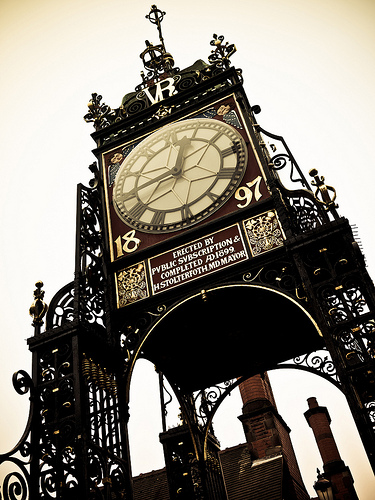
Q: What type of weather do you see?
A: It is cloudless.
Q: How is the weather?
A: It is cloudless.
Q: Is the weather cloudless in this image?
A: Yes, it is cloudless.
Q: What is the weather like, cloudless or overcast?
A: It is cloudless.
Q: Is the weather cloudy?
A: No, it is cloudless.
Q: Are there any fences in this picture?
A: No, there are no fences.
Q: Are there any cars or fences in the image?
A: No, there are no fences or cars.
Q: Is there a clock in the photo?
A: Yes, there is a clock.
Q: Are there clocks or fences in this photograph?
A: Yes, there is a clock.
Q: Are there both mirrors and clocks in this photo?
A: No, there is a clock but no mirrors.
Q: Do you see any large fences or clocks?
A: Yes, there is a large clock.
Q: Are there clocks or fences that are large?
A: Yes, the clock is large.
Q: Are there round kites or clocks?
A: Yes, there is a round clock.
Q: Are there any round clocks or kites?
A: Yes, there is a round clock.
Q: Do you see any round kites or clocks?
A: Yes, there is a round clock.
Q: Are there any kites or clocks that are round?
A: Yes, the clock is round.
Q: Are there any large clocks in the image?
A: Yes, there is a large clock.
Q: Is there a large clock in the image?
A: Yes, there is a large clock.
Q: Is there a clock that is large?
A: Yes, there is a clock that is large.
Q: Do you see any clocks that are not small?
A: Yes, there is a large clock.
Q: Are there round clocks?
A: Yes, there is a round clock.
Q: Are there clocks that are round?
A: Yes, there is a clock that is round.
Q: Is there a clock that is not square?
A: Yes, there is a round clock.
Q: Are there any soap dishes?
A: No, there are no soap dishes.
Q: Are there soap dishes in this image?
A: No, there are no soap dishes.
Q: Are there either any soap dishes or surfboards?
A: No, there are no soap dishes or surfboards.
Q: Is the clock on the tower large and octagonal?
A: No, the clock is large but round.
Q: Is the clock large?
A: Yes, the clock is large.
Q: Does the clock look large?
A: Yes, the clock is large.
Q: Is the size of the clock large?
A: Yes, the clock is large.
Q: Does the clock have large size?
A: Yes, the clock is large.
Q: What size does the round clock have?
A: The clock has large size.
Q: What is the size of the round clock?
A: The clock is large.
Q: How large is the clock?
A: The clock is large.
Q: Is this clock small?
A: No, the clock is large.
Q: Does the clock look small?
A: No, the clock is large.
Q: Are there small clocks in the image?
A: No, there is a clock but it is large.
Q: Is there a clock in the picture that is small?
A: No, there is a clock but it is large.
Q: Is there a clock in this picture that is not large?
A: No, there is a clock but it is large.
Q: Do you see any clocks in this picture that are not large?
A: No, there is a clock but it is large.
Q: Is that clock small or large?
A: The clock is large.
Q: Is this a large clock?
A: Yes, this is a large clock.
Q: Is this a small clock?
A: No, this is a large clock.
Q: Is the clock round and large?
A: Yes, the clock is round and large.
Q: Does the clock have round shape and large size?
A: Yes, the clock is round and large.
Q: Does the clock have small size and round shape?
A: No, the clock is round but large.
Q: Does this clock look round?
A: Yes, the clock is round.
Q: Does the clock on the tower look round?
A: Yes, the clock is round.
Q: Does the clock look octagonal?
A: No, the clock is round.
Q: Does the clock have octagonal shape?
A: No, the clock is round.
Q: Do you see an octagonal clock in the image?
A: No, there is a clock but it is round.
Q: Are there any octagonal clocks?
A: No, there is a clock but it is round.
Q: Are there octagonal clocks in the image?
A: No, there is a clock but it is round.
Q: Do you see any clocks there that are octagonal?
A: No, there is a clock but it is round.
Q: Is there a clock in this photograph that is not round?
A: No, there is a clock but it is round.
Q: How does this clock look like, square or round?
A: The clock is round.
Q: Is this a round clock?
A: Yes, this is a round clock.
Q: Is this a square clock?
A: No, this is a round clock.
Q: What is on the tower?
A: The clock is on the tower.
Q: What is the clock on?
A: The clock is on the tower.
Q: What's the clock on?
A: The clock is on the tower.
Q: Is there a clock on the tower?
A: Yes, there is a clock on the tower.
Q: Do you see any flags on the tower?
A: No, there is a clock on the tower.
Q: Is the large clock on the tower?
A: Yes, the clock is on the tower.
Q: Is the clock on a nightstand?
A: No, the clock is on the tower.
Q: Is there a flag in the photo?
A: No, there are no flags.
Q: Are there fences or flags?
A: No, there are no flags or fences.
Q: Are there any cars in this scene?
A: No, there are no cars.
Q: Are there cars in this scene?
A: No, there are no cars.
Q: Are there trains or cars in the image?
A: No, there are no cars or trains.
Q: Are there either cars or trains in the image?
A: No, there are no cars or trains.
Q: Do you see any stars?
A: Yes, there is a star.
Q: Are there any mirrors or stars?
A: Yes, there is a star.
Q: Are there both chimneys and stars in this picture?
A: Yes, there are both a star and a chimney.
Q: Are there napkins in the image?
A: No, there are no napkins.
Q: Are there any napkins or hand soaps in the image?
A: No, there are no napkins or hand soaps.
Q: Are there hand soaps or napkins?
A: No, there are no napkins or hand soaps.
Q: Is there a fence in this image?
A: No, there are no fences.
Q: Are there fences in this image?
A: No, there are no fences.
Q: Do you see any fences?
A: No, there are no fences.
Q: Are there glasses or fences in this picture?
A: No, there are no fences or glasses.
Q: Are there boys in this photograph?
A: No, there are no boys.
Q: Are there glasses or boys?
A: No, there are no boys or glasses.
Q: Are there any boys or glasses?
A: No, there are no boys or glasses.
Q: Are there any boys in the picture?
A: No, there are no boys.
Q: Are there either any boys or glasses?
A: No, there are no boys or glasses.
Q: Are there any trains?
A: No, there are no trains.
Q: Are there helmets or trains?
A: No, there are no trains or helmets.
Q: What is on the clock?
A: The number is on the clock.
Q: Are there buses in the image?
A: No, there are no buses.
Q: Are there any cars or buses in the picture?
A: No, there are no buses or cars.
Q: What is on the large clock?
A: The number is on the clock.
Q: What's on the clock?
A: The number is on the clock.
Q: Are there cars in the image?
A: No, there are no cars.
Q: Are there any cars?
A: No, there are no cars.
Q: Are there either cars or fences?
A: No, there are no cars or fences.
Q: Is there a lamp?
A: Yes, there is a lamp.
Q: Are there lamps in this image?
A: Yes, there is a lamp.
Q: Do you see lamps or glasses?
A: Yes, there is a lamp.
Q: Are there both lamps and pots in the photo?
A: No, there is a lamp but no pots.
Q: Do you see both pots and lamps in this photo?
A: No, there is a lamp but no pots.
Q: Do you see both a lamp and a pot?
A: No, there is a lamp but no pots.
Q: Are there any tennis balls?
A: No, there are no tennis balls.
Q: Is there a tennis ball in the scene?
A: No, there are no tennis balls.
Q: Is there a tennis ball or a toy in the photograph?
A: No, there are no tennis balls or toys.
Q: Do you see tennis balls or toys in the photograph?
A: No, there are no tennis balls or toys.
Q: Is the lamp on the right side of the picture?
A: Yes, the lamp is on the right of the image.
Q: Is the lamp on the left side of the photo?
A: No, the lamp is on the right of the image.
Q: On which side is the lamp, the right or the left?
A: The lamp is on the right of the image.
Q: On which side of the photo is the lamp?
A: The lamp is on the right of the image.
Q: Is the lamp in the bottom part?
A: Yes, the lamp is in the bottom of the image.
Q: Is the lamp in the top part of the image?
A: No, the lamp is in the bottom of the image.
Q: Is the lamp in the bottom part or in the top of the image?
A: The lamp is in the bottom of the image.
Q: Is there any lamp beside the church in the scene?
A: Yes, there is a lamp beside the church.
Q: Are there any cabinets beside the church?
A: No, there is a lamp beside the church.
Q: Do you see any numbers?
A: Yes, there are numbers.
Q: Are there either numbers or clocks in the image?
A: Yes, there are numbers.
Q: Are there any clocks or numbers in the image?
A: Yes, there are numbers.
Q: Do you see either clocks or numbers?
A: Yes, there are numbers.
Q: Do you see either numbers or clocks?
A: Yes, there are numbers.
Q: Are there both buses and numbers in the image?
A: No, there are numbers but no buses.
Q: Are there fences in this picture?
A: No, there are no fences.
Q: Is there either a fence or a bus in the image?
A: No, there are no fences or buses.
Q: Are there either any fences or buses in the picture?
A: No, there are no fences or buses.